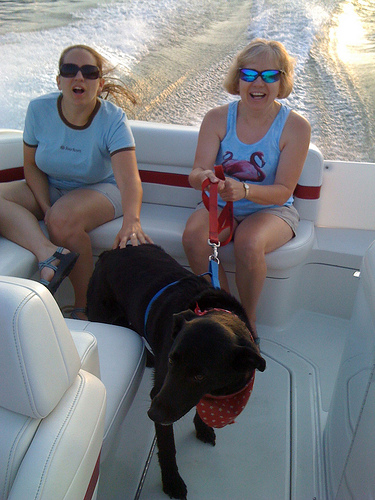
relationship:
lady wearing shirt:
[0, 44, 154, 322] [21, 90, 137, 192]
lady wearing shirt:
[180, 41, 310, 346] [211, 99, 293, 209]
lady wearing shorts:
[0, 44, 154, 322] [48, 181, 124, 216]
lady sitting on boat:
[180, 41, 310, 346] [1, 119, 374, 498]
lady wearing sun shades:
[0, 44, 154, 322] [54, 60, 101, 81]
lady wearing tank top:
[180, 41, 310, 346] [204, 98, 294, 217]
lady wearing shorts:
[0, 44, 154, 322] [173, 188, 306, 242]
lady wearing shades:
[180, 41, 310, 346] [230, 62, 290, 83]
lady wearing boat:
[180, 41, 310, 346] [1, 119, 374, 498]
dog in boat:
[84, 242, 267, 499] [1, 119, 374, 498]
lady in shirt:
[0, 44, 154, 322] [202, 102, 294, 216]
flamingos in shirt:
[217, 148, 265, 179] [202, 102, 293, 215]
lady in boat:
[165, 62, 318, 308] [39, 76, 370, 358]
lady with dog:
[180, 41, 310, 346] [84, 242, 267, 499]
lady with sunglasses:
[180, 41, 310, 346] [238, 63, 283, 83]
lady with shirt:
[180, 41, 310, 346] [203, 98, 296, 222]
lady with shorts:
[180, 41, 310, 346] [193, 191, 302, 240]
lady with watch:
[180, 41, 310, 346] [238, 178, 252, 202]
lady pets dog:
[0, 44, 154, 322] [84, 242, 267, 499]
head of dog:
[147, 309, 263, 426] [84, 242, 267, 499]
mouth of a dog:
[148, 383, 203, 425] [84, 242, 267, 499]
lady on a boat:
[180, 41, 310, 346] [1, 119, 374, 498]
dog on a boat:
[84, 242, 267, 499] [1, 119, 374, 498]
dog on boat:
[83, 222, 305, 497] [1, 119, 374, 498]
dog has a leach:
[84, 242, 267, 499] [196, 163, 238, 295]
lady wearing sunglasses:
[0, 44, 154, 322] [236, 65, 283, 83]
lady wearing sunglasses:
[180, 41, 310, 346] [236, 65, 283, 83]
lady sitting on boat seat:
[0, 44, 154, 322] [0, 199, 313, 276]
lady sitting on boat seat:
[180, 41, 310, 346] [0, 199, 313, 276]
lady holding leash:
[180, 41, 310, 346] [199, 163, 235, 264]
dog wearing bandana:
[84, 242, 267, 499] [198, 306, 252, 430]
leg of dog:
[146, 358, 196, 494] [84, 242, 267, 499]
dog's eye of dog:
[165, 355, 207, 388] [84, 242, 267, 499]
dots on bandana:
[196, 383, 251, 425] [195, 362, 259, 426]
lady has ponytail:
[0, 44, 156, 322] [99, 79, 139, 111]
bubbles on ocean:
[62, 5, 154, 46] [0, 1, 374, 161]